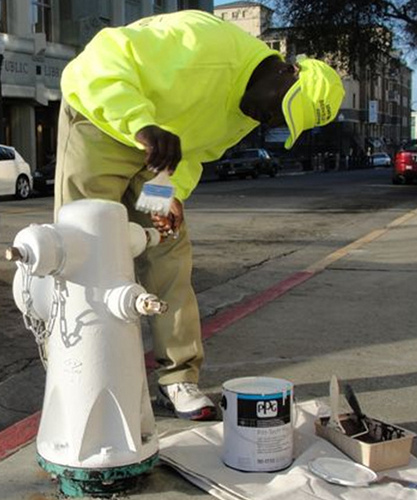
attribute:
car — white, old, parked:
[3, 140, 36, 204]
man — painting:
[117, 21, 335, 352]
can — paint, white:
[231, 359, 298, 470]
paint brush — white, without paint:
[135, 167, 169, 223]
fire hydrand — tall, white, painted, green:
[30, 200, 171, 461]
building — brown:
[14, 12, 73, 101]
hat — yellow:
[287, 50, 343, 132]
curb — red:
[213, 291, 264, 332]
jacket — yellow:
[130, 13, 239, 148]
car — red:
[385, 141, 417, 192]